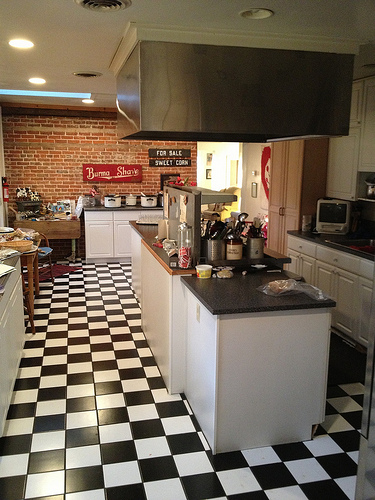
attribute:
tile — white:
[168, 445, 219, 478]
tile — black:
[179, 471, 228, 498]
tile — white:
[172, 448, 217, 478]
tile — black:
[178, 473, 220, 498]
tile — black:
[136, 455, 184, 482]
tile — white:
[140, 474, 187, 498]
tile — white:
[64, 443, 103, 472]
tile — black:
[61, 462, 103, 498]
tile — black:
[205, 445, 246, 475]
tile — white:
[210, 464, 263, 494]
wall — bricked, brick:
[1, 112, 199, 263]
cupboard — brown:
[264, 134, 333, 264]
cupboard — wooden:
[264, 138, 330, 270]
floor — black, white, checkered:
[5, 254, 373, 497]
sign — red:
[77, 158, 143, 188]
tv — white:
[312, 194, 352, 238]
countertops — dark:
[179, 271, 339, 322]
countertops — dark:
[283, 222, 373, 267]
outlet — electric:
[191, 306, 203, 318]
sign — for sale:
[146, 144, 188, 161]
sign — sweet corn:
[146, 158, 195, 168]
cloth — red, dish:
[350, 241, 373, 253]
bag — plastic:
[259, 275, 328, 303]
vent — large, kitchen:
[107, 32, 359, 149]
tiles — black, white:
[5, 250, 373, 497]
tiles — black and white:
[61, 376, 157, 491]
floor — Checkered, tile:
[34, 288, 146, 474]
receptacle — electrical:
[194, 302, 200, 322]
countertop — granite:
[181, 273, 337, 315]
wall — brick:
[25, 115, 110, 191]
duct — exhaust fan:
[107, 59, 353, 142]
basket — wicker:
[3, 238, 35, 252]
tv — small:
[314, 196, 351, 238]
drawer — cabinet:
[310, 245, 361, 279]